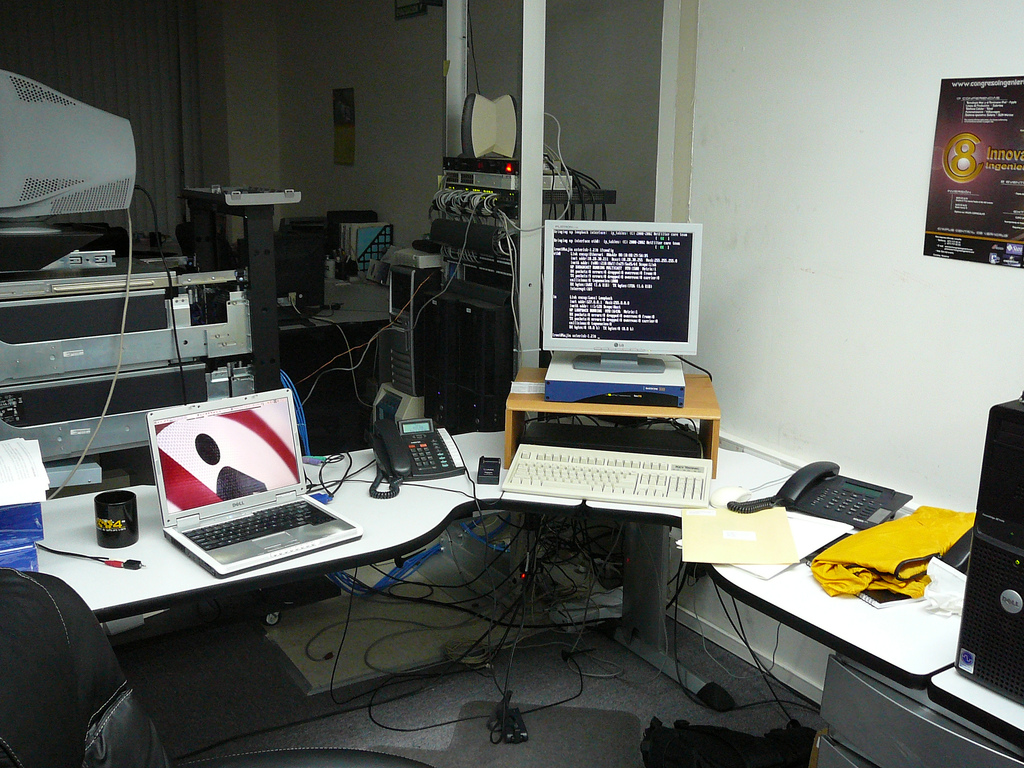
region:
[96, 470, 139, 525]
Black mug on the top of the table.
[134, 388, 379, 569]
Silver computer on the table.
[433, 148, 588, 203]
Silver DVD player on the desk.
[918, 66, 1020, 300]
Small poster on the side of the wall.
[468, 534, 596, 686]
Group of cords under the table.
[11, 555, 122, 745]
Black chair behind the table.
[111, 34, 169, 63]
Group of blinds by the wall.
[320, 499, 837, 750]
jumbled up wires under your desk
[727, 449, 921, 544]
office telephone with all the features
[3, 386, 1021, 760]
convienant corner style computer desk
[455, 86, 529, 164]
dual sided audio speakers, white with gray facing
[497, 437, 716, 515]
white, full size keybroad, with number pad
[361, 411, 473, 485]
professional office phone with digital display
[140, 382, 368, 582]
office laptop in working order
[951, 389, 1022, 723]
Dell Computer tower in black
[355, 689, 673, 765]
plastic computer chair floor protector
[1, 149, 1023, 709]
electronic office equipment storing data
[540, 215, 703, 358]
A white framed monitor.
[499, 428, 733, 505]
A white computer keyboard.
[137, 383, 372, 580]
A laptop on the desk.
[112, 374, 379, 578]
A silver and black laptop.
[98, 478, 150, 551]
A black mug with yellow writing on it.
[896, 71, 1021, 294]
A flyer on the wall.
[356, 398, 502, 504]
A corded black telephone.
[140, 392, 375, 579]
laptop is open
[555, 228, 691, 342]
white writing on a black background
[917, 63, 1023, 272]
poster is hanging on the wall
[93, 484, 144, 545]
black mug with a yellow design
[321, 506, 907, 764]
several wires are on the floor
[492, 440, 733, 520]
large white keyboard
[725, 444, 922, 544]
black phone is on the desk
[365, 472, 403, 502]
cord hanging off the phone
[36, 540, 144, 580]
cord laying on the desk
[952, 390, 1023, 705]
black computer tower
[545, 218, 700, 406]
A computer monitor.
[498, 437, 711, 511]
A keyboard.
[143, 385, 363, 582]
An open laptop computer.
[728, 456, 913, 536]
A telephone.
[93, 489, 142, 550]
A black coffee mug with yellow letters.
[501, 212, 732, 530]
A computer monitor on a stand with a keyboard below it.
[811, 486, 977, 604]
Some folded yellow fabric.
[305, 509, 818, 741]
A jumble of cords below a desk.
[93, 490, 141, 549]
black and yellow coffee mug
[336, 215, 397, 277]
file folders in black magazine case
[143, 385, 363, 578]
silver laptop computer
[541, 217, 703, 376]
flat screen computer monitor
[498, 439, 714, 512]
white desktop computer keyboard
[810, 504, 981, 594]
folded yellow textile material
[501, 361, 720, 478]
brown wooden computer riser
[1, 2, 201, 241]
white vertical window blinds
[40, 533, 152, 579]
electronic equipment on desk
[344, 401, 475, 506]
electronic equipment on desk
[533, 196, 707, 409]
electronic equipment on desk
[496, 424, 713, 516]
electronic equipment on desk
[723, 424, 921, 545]
electronic equipment on desk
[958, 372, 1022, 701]
electronic equipment on desk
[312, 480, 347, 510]
electronic equipment on desk